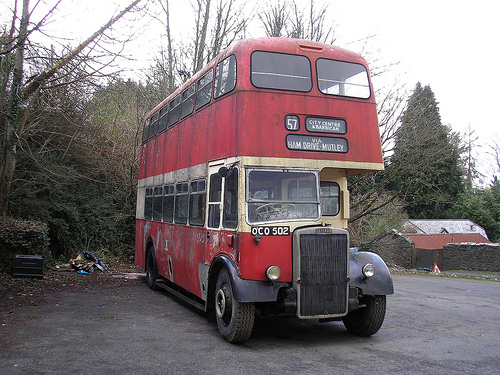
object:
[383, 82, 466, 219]
tree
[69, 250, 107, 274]
pile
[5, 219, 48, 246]
limbs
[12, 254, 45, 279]
bin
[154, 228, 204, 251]
rust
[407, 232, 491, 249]
roof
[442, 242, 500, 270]
wall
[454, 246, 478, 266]
rocks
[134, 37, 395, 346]
bus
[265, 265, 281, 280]
headlight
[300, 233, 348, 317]
gril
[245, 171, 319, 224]
windshield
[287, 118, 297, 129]
number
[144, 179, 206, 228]
windows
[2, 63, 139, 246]
trees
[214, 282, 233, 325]
rim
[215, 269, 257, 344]
tire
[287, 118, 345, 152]
text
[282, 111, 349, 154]
background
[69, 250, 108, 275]
debris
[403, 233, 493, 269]
houses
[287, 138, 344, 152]
letters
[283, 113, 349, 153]
sign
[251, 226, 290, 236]
license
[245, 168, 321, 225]
window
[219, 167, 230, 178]
mirror